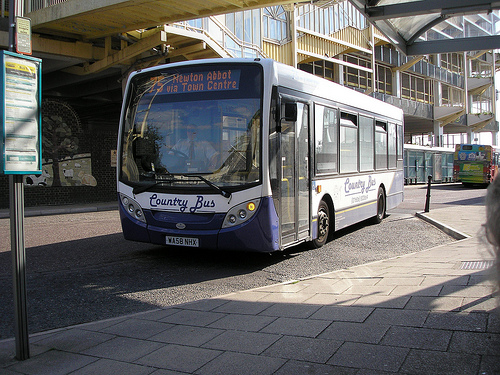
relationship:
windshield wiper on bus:
[180, 172, 231, 198] [111, 53, 427, 264]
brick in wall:
[45, 109, 92, 146] [0, 79, 117, 204]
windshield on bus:
[120, 98, 265, 186] [116, 57, 404, 253]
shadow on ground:
[0, 181, 496, 372] [377, 247, 418, 309]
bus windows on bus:
[313, 101, 404, 176] [116, 57, 404, 253]